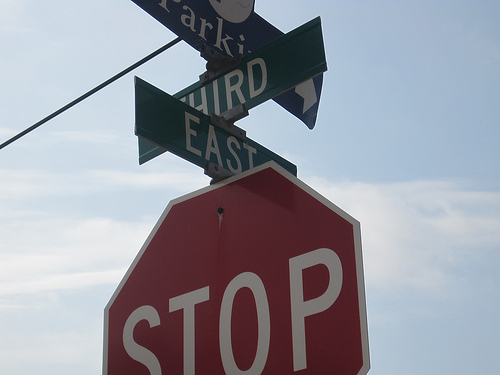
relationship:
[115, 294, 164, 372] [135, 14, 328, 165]
letter on sign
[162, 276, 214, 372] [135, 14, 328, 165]
letter on sign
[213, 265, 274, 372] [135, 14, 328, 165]
letter o on sign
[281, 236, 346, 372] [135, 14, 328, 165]
letter p on sign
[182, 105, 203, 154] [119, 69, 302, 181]
letter on sign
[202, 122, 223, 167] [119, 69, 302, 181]
letter on sign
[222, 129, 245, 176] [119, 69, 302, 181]
letter on sign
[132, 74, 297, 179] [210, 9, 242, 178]
sign on pole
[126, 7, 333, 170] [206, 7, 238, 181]
sign on pole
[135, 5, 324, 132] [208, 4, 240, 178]
sign on pole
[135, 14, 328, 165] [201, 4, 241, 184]
sign on pole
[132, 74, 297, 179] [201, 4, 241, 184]
sign on pole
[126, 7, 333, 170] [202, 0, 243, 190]
sign on pole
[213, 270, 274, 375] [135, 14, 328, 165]
letter o on sign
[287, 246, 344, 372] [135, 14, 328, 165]
letter p on sign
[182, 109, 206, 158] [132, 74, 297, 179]
letter on sign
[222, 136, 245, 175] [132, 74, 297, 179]
letter on sign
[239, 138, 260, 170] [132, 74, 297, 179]
letter on sign